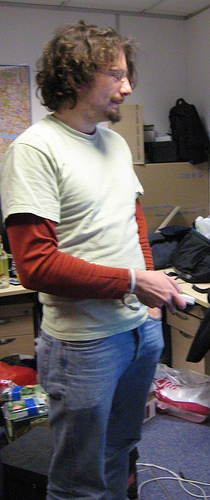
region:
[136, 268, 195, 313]
a man's right hand holding a white object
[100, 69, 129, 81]
eyeglasses on the man's face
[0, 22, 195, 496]
a man wearing blue jeans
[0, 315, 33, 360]
2 light brown drawers with handles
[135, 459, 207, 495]
gray electrical cords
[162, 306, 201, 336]
a light brown partially opened drawer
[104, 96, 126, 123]
a man with facial hair above and below the lips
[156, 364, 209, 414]
a red and white plastic bag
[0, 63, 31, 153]
a map on the wall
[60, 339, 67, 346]
a rivet on the corner of a front pocket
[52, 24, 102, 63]
shaggy brown hair on a head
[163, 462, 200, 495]
a white cord on the floor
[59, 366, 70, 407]
a seam on the leg of jeans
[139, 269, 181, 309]
a hand holding a game controller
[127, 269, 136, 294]
a white strp on a wrist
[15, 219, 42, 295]
a red sleeve covering an arm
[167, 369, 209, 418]
a red and white plastic bag on the floor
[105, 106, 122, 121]
a brown goatee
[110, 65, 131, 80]
glasses on a face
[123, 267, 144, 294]
the band is white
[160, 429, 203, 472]
the carpet is grey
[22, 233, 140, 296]
the sleeves are orange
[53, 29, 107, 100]
the hair is brown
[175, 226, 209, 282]
the bag is black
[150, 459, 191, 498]
the wires are white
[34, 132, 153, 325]
the shirt is cream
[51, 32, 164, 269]
the guy has glasses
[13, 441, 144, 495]
the box is closed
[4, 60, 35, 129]
map is on the wall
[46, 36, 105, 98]
The man has curly hair.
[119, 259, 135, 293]
The man is wearing a whit waistband.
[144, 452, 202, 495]
The cord is on the floor.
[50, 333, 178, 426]
The man is wearing jeans.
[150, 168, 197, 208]
Cardboard boxes folded up.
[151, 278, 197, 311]
The man has the contoller in hand.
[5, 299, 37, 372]
The drawers on the cabinet.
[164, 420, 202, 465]
The rug is blue.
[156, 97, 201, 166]
A backpack on the box.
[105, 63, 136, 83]
The man is wearing glasses.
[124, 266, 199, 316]
person's hand holding a wii remote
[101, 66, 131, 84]
man wearing glasses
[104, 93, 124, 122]
man with a mustache and goatee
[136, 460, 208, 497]
electrical cords on a blue carpet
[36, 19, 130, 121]
man with curly hair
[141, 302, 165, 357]
man with his hand in his pocket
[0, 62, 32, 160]
map on a wall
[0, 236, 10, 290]
glass bottle on a desk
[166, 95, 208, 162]
backpack on top of a large cardboard box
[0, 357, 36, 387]
red bag on the floor